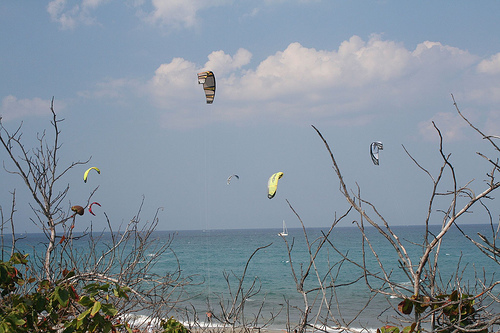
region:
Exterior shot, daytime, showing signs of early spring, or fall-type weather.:
[7, 15, 499, 331]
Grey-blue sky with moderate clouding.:
[57, 14, 458, 205]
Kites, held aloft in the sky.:
[79, 68, 399, 215]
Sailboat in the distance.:
[274, 220, 295, 246]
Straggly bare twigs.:
[18, 119, 465, 269]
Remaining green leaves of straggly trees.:
[12, 255, 151, 331]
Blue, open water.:
[181, 229, 303, 287]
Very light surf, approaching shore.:
[159, 315, 356, 331]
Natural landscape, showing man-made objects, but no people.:
[8, 12, 499, 319]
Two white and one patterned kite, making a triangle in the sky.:
[79, 67, 309, 210]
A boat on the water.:
[276, 207, 296, 242]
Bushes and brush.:
[7, 249, 498, 331]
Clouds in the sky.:
[156, 35, 483, 112]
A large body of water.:
[21, 221, 473, 300]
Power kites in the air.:
[77, 137, 395, 203]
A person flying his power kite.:
[193, 298, 227, 327]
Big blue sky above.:
[13, 0, 482, 164]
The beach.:
[101, 310, 324, 331]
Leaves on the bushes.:
[13, 258, 194, 331]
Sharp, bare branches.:
[306, 165, 496, 259]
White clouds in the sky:
[230, 19, 397, 150]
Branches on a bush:
[323, 165, 483, 300]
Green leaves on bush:
[11, 278, 134, 331]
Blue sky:
[27, 38, 180, 119]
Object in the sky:
[161, 51, 261, 140]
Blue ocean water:
[174, 228, 265, 282]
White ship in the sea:
[253, 224, 316, 261]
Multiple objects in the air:
[45, 58, 313, 224]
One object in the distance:
[211, 162, 256, 222]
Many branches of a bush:
[296, 144, 499, 281]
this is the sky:
[6, 3, 45, 83]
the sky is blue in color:
[8, 62, 37, 84]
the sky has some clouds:
[260, 50, 462, 100]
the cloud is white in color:
[289, 52, 333, 83]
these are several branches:
[11, 125, 118, 275]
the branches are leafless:
[29, 136, 66, 222]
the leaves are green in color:
[48, 287, 120, 329]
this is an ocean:
[193, 231, 230, 289]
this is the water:
[179, 232, 233, 254]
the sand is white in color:
[136, 315, 149, 330]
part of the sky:
[313, 0, 352, 31]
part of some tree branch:
[353, 192, 396, 282]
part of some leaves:
[73, 298, 110, 325]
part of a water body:
[239, 237, 281, 283]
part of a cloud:
[276, 47, 306, 80]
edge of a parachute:
[193, 80, 205, 93]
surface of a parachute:
[265, 167, 285, 197]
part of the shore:
[243, 313, 269, 328]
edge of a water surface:
[213, 220, 238, 235]